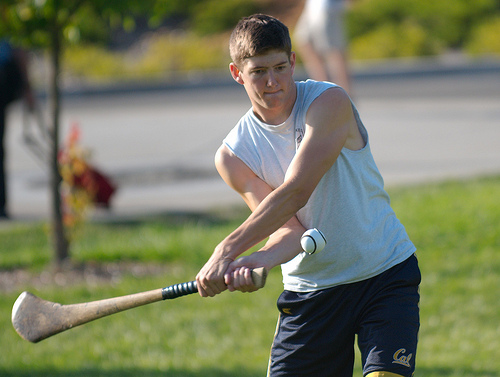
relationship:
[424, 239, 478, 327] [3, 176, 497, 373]
green grass in field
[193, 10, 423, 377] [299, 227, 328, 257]
boy looking at black stripes ball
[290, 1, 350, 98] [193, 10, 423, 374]
person walking behind boy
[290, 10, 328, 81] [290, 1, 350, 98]
leg belonging to person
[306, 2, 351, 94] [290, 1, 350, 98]
leg belonging to person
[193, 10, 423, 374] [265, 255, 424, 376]
boy wearing blue shorts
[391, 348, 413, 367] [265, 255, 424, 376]
cal sewn on blue shorts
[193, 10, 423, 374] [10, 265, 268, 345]
boy holding bat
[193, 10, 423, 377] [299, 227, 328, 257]
boy hitting black stripes ball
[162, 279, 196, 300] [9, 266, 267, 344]
grip wrapped around bat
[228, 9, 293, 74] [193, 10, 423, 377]
hair belonging to boy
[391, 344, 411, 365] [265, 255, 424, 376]
cal sewn on blue shorts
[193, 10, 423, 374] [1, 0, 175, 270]
boy playing in front of tree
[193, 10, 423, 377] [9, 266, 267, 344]
boy swinging bat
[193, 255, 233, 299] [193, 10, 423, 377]
hand belonging to boy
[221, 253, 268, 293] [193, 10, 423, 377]
hand belonging to boy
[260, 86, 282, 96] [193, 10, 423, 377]
mouth belonging to boy